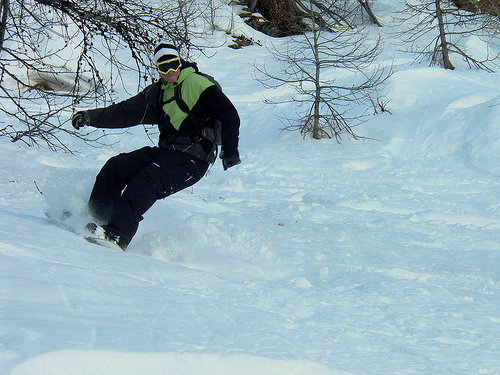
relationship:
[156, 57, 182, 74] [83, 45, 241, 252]
goggles are worn by man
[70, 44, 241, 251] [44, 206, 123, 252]
man riding skis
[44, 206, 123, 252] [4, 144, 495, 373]
skis in snow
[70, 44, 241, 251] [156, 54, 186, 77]
man wearing googles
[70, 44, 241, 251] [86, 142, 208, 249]
man wearing pants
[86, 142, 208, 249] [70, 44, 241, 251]
pants on man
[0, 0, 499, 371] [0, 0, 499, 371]
snow on hill side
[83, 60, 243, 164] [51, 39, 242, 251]
jacket on man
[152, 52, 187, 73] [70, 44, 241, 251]
goggles on man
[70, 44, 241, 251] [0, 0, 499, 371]
man in snow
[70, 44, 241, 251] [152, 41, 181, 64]
man wearing hat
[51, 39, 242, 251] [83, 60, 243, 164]
man wearing jacket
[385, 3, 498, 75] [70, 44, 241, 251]
tree to right of man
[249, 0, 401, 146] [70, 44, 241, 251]
tree to right of man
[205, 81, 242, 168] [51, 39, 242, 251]
left arm of man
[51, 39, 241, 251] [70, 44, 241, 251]
right arm of man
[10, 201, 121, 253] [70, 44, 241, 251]
skis on man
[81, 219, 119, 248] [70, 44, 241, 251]
foot on man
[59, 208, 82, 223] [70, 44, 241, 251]
foot on man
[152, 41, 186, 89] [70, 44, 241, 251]
head on man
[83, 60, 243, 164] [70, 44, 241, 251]
jacket on man